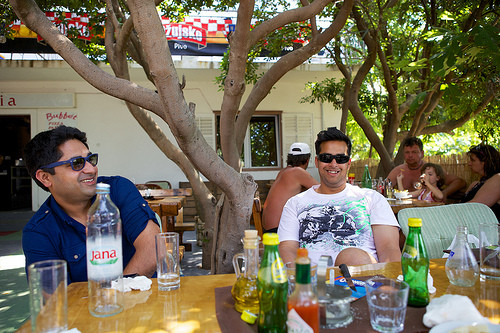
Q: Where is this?
A: This is at the restaurant.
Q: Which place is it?
A: It is a restaurant.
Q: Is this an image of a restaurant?
A: Yes, it is showing a restaurant.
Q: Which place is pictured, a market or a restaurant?
A: It is a restaurant.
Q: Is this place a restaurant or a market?
A: It is a restaurant.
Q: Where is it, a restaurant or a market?
A: It is a restaurant.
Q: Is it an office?
A: No, it is a restaurant.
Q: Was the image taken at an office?
A: No, the picture was taken in a restaurant.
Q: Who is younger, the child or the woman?
A: The child is younger than the woman.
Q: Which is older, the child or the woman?
A: The woman is older than the child.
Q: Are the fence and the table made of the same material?
A: Yes, both the fence and the table are made of wood.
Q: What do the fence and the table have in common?
A: The material, both the fence and the table are wooden.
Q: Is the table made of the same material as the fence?
A: Yes, both the table and the fence are made of wood.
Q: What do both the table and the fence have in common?
A: The material, both the table and the fence are wooden.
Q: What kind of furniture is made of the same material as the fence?
A: The table is made of the same material as the fence.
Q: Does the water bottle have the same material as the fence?
A: No, the water bottle is made of plastic and the fence is made of wood.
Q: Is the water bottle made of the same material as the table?
A: No, the water bottle is made of plastic and the table is made of wood.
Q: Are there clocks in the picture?
A: No, there are no clocks.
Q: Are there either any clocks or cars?
A: No, there are no clocks or cars.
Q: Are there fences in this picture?
A: Yes, there is a fence.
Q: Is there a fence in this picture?
A: Yes, there is a fence.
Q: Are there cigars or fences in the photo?
A: Yes, there is a fence.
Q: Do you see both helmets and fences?
A: No, there is a fence but no helmets.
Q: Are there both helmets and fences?
A: No, there is a fence but no helmets.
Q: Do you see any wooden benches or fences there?
A: Yes, there is a wood fence.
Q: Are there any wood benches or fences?
A: Yes, there is a wood fence.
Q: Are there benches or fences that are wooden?
A: Yes, the fence is wooden.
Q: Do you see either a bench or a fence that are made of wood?
A: Yes, the fence is made of wood.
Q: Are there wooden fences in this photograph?
A: Yes, there is a wood fence.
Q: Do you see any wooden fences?
A: Yes, there is a wood fence.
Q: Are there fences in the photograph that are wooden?
A: Yes, there is a fence that is wooden.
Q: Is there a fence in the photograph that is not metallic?
A: Yes, there is a wooden fence.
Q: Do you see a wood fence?
A: Yes, there is a fence that is made of wood.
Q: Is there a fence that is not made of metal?
A: Yes, there is a fence that is made of wood.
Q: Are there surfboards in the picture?
A: No, there are no surfboards.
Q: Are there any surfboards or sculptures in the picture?
A: No, there are no surfboards or sculptures.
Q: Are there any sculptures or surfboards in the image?
A: No, there are no surfboards or sculptures.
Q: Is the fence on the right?
A: Yes, the fence is on the right of the image.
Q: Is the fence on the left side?
A: No, the fence is on the right of the image.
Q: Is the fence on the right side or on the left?
A: The fence is on the right of the image.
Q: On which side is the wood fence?
A: The fence is on the right of the image.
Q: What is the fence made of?
A: The fence is made of wood.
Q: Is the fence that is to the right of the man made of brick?
A: No, the fence is made of wood.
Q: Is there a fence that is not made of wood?
A: No, there is a fence but it is made of wood.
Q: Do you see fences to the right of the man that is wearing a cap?
A: Yes, there is a fence to the right of the man.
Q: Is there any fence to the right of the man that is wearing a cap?
A: Yes, there is a fence to the right of the man.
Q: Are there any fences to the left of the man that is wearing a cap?
A: No, the fence is to the right of the man.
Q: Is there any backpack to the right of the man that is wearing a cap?
A: No, there is a fence to the right of the man.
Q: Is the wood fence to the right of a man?
A: Yes, the fence is to the right of a man.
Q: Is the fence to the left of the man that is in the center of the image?
A: No, the fence is to the right of the man.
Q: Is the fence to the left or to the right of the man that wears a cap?
A: The fence is to the right of the man.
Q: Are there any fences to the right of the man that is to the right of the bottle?
A: Yes, there is a fence to the right of the man.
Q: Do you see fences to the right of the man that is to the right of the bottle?
A: Yes, there is a fence to the right of the man.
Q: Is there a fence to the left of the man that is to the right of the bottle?
A: No, the fence is to the right of the man.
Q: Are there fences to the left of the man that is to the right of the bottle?
A: No, the fence is to the right of the man.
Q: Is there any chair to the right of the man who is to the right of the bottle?
A: No, there is a fence to the right of the man.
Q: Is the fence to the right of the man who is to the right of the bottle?
A: Yes, the fence is to the right of the man.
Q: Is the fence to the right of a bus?
A: No, the fence is to the right of the man.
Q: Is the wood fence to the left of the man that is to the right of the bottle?
A: No, the fence is to the right of the man.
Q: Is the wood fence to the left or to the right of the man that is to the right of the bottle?
A: The fence is to the right of the man.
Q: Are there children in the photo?
A: Yes, there is a child.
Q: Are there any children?
A: Yes, there is a child.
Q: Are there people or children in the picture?
A: Yes, there is a child.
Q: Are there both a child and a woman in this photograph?
A: Yes, there are both a child and a woman.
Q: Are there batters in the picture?
A: No, there are no batters.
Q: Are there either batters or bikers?
A: No, there are no batters or bikers.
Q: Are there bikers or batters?
A: No, there are no batters or bikers.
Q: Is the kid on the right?
A: Yes, the kid is on the right of the image.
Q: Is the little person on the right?
A: Yes, the kid is on the right of the image.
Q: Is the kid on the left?
A: No, the kid is on the right of the image.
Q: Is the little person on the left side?
A: No, the kid is on the right of the image.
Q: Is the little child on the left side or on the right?
A: The child is on the right of the image.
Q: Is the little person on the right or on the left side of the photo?
A: The child is on the right of the image.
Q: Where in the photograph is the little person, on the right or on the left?
A: The child is on the right of the image.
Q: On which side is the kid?
A: The kid is on the right of the image.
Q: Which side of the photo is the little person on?
A: The kid is on the right of the image.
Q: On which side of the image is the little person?
A: The kid is on the right of the image.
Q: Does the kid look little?
A: Yes, the kid is little.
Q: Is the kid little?
A: Yes, the kid is little.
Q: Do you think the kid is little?
A: Yes, the kid is little.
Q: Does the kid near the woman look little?
A: Yes, the kid is little.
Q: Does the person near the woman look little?
A: Yes, the kid is little.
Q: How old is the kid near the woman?
A: The kid is little.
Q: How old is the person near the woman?
A: The kid is little.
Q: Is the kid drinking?
A: Yes, the kid is drinking.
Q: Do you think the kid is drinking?
A: Yes, the kid is drinking.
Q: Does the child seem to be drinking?
A: Yes, the child is drinking.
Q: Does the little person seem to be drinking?
A: Yes, the child is drinking.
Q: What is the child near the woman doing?
A: The kid is drinking.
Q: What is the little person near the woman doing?
A: The kid is drinking.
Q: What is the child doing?
A: The kid is drinking.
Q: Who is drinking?
A: The child is drinking.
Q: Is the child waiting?
A: No, the child is drinking.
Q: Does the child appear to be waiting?
A: No, the child is drinking.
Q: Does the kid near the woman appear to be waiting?
A: No, the child is drinking.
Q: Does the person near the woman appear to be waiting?
A: No, the child is drinking.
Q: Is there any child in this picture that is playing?
A: No, there is a child but he is drinking.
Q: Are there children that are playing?
A: No, there is a child but he is drinking.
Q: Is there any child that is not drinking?
A: No, there is a child but he is drinking.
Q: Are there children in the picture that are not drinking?
A: No, there is a child but he is drinking.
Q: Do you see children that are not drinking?
A: No, there is a child but he is drinking.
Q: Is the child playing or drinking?
A: The child is drinking.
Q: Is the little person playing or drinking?
A: The child is drinking.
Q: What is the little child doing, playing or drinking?
A: The kid is drinking.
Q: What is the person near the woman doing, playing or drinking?
A: The kid is drinking.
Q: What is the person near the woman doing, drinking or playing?
A: The kid is drinking.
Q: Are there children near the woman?
A: Yes, there is a child near the woman.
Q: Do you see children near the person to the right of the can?
A: Yes, there is a child near the woman.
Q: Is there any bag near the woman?
A: No, there is a child near the woman.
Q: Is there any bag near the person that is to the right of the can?
A: No, there is a child near the woman.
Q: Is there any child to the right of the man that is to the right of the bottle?
A: Yes, there is a child to the right of the man.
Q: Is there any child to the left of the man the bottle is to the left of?
A: No, the child is to the right of the man.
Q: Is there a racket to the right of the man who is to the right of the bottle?
A: No, there is a child to the right of the man.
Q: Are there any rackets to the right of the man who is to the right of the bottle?
A: No, there is a child to the right of the man.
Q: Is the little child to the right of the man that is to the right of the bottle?
A: Yes, the child is to the right of the man.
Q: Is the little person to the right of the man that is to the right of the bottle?
A: Yes, the child is to the right of the man.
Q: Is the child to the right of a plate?
A: No, the child is to the right of the man.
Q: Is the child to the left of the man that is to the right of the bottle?
A: No, the child is to the right of the man.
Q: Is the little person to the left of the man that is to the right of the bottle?
A: No, the child is to the right of the man.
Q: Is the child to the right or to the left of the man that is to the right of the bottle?
A: The child is to the right of the man.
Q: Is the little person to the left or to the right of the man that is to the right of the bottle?
A: The child is to the right of the man.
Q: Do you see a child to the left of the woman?
A: Yes, there is a child to the left of the woman.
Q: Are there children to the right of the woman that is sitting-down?
A: No, the child is to the left of the woman.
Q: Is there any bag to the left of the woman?
A: No, there is a child to the left of the woman.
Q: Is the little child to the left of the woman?
A: Yes, the kid is to the left of the woman.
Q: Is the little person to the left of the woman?
A: Yes, the kid is to the left of the woman.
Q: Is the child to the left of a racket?
A: No, the child is to the left of the woman.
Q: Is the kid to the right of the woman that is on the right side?
A: No, the kid is to the left of the woman.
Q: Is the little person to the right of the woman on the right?
A: No, the kid is to the left of the woman.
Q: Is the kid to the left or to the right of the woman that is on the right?
A: The kid is to the left of the woman.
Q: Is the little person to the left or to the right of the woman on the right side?
A: The kid is to the left of the woman.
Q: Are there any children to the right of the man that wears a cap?
A: Yes, there is a child to the right of the man.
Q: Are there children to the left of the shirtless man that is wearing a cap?
A: No, the child is to the right of the man.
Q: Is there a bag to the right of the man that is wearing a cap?
A: No, there is a child to the right of the man.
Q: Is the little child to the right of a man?
A: Yes, the child is to the right of a man.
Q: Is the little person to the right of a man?
A: Yes, the child is to the right of a man.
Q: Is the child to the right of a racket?
A: No, the child is to the right of a man.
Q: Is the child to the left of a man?
A: No, the child is to the right of a man.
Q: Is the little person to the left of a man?
A: No, the child is to the right of a man.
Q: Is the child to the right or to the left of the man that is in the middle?
A: The child is to the right of the man.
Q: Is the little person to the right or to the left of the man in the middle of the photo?
A: The child is to the right of the man.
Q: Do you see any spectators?
A: No, there are no spectators.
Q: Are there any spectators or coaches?
A: No, there are no spectators or coaches.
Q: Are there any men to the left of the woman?
A: Yes, there is a man to the left of the woman.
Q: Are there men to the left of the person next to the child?
A: Yes, there is a man to the left of the woman.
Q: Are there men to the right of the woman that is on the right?
A: No, the man is to the left of the woman.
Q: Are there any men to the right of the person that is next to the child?
A: No, the man is to the left of the woman.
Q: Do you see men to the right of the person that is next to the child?
A: No, the man is to the left of the woman.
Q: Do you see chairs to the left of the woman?
A: No, there is a man to the left of the woman.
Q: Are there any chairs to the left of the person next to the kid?
A: No, there is a man to the left of the woman.